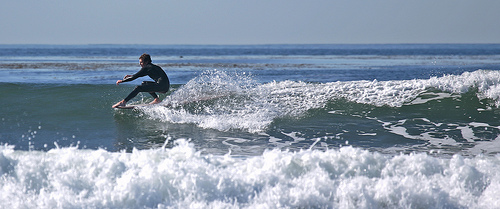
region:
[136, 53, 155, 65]
a head on a man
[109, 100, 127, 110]
a foot on a man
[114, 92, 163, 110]
a surfboard under a man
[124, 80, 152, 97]
a bent leg on a man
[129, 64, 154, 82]
an outstretched arm on a man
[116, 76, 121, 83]
a hand on a man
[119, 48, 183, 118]
a man wearing a black wetsuit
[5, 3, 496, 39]
a grey blue sky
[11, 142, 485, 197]
white waves crashing to shore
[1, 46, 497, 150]
blue ocean water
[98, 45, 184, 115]
Guy surfing in the ocean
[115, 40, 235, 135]
Surfing all the way to the beach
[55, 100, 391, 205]
waves splashing across the ocean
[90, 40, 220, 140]
Surf's up, crossing the wave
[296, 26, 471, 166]
Ocean waves roaring across the water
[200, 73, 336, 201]
saltwater all across the ocean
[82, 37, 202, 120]
Surfing a wave, like a pro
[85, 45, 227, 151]
Fun time hanging the waves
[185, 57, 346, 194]
Splashing waves in the ocean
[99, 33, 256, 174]
Guy, surfing the waves smoothly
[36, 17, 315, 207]
a man is surfing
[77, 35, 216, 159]
a man is surfing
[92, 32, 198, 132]
man surfing in ocean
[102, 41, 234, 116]
man wearing a black wetsuit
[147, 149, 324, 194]
white caps of waves crashing to ocean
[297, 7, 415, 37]
grey clear sky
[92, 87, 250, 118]
long white surfboard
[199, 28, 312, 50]
where the ocean and sky meet to form horizon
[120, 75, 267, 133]
splashing water caused by surfboard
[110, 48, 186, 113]
mans foot on top of surfboard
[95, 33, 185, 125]
one surfer in ocean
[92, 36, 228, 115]
man hunched down on surfboard